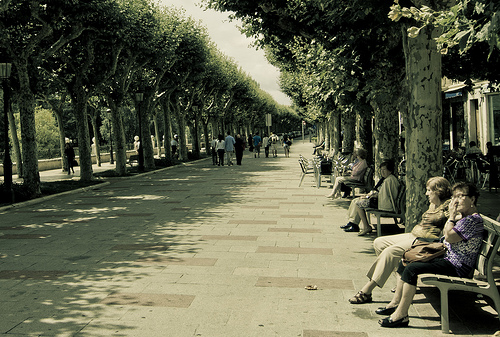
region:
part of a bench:
[449, 298, 454, 318]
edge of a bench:
[488, 272, 497, 287]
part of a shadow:
[119, 184, 129, 240]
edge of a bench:
[309, 161, 315, 170]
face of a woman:
[451, 195, 464, 217]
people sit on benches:
[300, 128, 498, 310]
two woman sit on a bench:
[344, 169, 498, 324]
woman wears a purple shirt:
[443, 180, 493, 297]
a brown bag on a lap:
[402, 229, 453, 274]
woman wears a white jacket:
[371, 160, 401, 216]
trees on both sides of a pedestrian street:
[7, 5, 481, 232]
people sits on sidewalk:
[430, 125, 498, 184]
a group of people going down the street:
[200, 120, 296, 165]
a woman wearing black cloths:
[57, 128, 82, 174]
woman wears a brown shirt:
[403, 172, 454, 240]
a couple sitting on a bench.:
[359, 146, 481, 334]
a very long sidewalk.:
[41, 135, 451, 335]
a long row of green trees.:
[0, 0, 294, 226]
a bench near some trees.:
[293, 129, 326, 194]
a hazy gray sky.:
[127, 0, 299, 112]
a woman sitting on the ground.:
[381, 180, 486, 328]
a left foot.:
[346, 280, 383, 305]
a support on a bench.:
[427, 276, 455, 334]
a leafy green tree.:
[198, 0, 498, 270]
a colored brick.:
[239, 260, 333, 294]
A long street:
[28, 155, 323, 324]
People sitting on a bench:
[346, 171, 498, 326]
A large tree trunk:
[402, 20, 448, 236]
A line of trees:
[11, 67, 269, 184]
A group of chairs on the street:
[292, 145, 360, 183]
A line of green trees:
[245, 18, 416, 134]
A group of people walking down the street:
[203, 125, 291, 166]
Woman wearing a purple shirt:
[441, 211, 487, 268]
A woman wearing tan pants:
[366, 225, 420, 302]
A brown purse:
[403, 240, 450, 265]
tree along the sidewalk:
[64, 18, 104, 188]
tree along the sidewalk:
[12, 18, 54, 195]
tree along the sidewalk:
[129, 77, 160, 163]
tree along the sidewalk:
[152, 83, 186, 165]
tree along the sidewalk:
[170, 88, 194, 159]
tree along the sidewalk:
[181, 89, 203, 154]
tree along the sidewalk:
[402, 67, 431, 210]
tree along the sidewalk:
[366, 75, 408, 178]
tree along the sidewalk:
[326, 70, 363, 149]